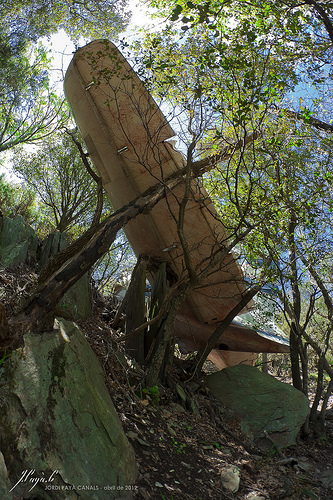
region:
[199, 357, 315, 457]
A large rock on a hillside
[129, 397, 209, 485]
Leaves lying in the dirt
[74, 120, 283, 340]
A wrecked playing in the trees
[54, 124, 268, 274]
A tree holding up a plane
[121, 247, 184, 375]
A dead split open tree trunk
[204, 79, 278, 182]
Leaf covered branches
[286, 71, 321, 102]
Blue sky visible through trees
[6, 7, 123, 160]
White cloud in the sky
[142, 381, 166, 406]
Moss growing against the base of a tree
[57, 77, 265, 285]
The wing of an airplane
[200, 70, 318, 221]
Leaves are green color.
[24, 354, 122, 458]
Rocks are green color.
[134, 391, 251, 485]
Ground is brown color.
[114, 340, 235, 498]
Dried leaves are in ground.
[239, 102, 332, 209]
Sky is blue color.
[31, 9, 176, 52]
Clouds are white color.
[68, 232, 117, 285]
Woods are brown color.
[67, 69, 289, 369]
Board is broken.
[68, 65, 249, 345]
Board is hanging in between the branches.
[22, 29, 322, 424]
Day time picture.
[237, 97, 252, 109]
a green tree leaf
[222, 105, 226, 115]
a green tree leaf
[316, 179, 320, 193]
a green tree leaf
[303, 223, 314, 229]
a green tree leaf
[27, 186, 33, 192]
a green tree leaf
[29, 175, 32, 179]
a green tree leaf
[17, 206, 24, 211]
a green tree leaf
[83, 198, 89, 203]
a green tree leaf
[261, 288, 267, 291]
a green tree leaf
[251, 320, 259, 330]
a green tree leaf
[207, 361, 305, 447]
a stone in the ground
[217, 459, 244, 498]
a stone in the ground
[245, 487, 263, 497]
a stone in the ground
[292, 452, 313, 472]
a stone in the ground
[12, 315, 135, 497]
a stone in the ground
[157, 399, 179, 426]
a stone in the ground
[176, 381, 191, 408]
a stone in the ground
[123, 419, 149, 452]
a stone in the ground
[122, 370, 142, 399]
a stone in the ground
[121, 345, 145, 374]
a stone in the ground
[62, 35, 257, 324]
Wing of an airplane.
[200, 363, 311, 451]
Green rock under an airplane wing.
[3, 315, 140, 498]
Large rock on the left bottom side of the photo.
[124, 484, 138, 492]
The year 2012 on a photo.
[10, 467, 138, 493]
Watermark on the bottom left of the picture.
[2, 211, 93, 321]
Two large boulders on the middle left.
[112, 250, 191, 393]
Three tree stumps under the plane wing.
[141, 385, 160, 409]
Green weeds directly under the stumps in the middle.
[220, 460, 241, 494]
Small gray rock on the bottom middle right.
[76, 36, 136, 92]
Small group of green leaves in front of the top of the wing.